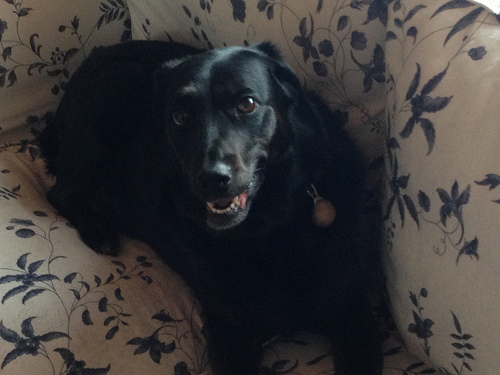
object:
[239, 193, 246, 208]
tongue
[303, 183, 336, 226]
tag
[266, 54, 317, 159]
ear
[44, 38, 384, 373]
black dog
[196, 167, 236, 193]
nose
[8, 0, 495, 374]
couch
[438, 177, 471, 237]
floral design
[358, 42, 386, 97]
floral design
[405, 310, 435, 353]
floral design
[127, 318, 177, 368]
floral design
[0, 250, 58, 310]
floral design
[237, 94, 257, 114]
eye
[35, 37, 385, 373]
dog's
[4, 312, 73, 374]
flower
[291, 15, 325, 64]
flower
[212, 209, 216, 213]
teeth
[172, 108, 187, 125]
eye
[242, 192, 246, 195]
gum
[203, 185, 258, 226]
mouth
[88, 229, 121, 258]
paw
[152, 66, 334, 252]
collar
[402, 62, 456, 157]
flower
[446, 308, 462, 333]
leaf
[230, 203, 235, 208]
teeth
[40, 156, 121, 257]
leg